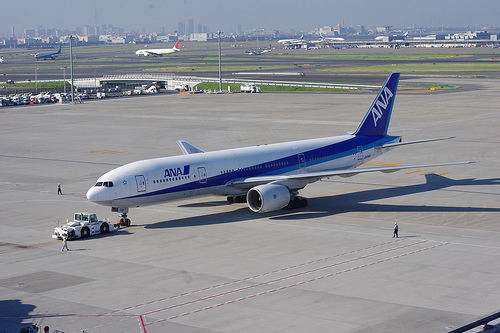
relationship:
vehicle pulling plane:
[53, 209, 116, 241] [69, 65, 477, 217]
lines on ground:
[100, 235, 435, 320] [3, 155, 446, 326]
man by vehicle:
[57, 232, 74, 249] [53, 209, 116, 241]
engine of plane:
[241, 183, 300, 216] [69, 65, 477, 217]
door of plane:
[132, 173, 147, 194] [69, 65, 477, 217]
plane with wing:
[69, 65, 477, 217] [228, 158, 479, 189]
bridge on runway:
[54, 64, 201, 92] [4, 66, 495, 88]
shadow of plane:
[141, 164, 499, 237] [69, 65, 477, 217]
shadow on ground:
[141, 164, 499, 237] [3, 155, 446, 326]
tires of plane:
[114, 213, 133, 227] [69, 65, 477, 217]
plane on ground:
[69, 65, 477, 217] [3, 155, 446, 326]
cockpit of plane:
[92, 180, 118, 191] [69, 65, 477, 217]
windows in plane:
[148, 148, 349, 194] [69, 65, 477, 217]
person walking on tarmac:
[55, 180, 66, 202] [0, 95, 499, 329]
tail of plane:
[352, 68, 456, 150] [69, 65, 477, 217]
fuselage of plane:
[135, 119, 407, 212] [69, 65, 477, 217]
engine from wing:
[241, 183, 300, 216] [228, 158, 479, 189]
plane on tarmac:
[69, 65, 477, 217] [0, 95, 499, 329]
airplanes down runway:
[23, 41, 318, 57] [4, 66, 495, 88]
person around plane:
[55, 182, 63, 196] [69, 65, 477, 217]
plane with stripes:
[69, 65, 477, 217] [259, 141, 329, 173]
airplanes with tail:
[134, 39, 182, 59] [169, 38, 182, 53]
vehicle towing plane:
[53, 209, 116, 241] [69, 65, 477, 217]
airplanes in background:
[23, 41, 318, 57] [9, 47, 488, 50]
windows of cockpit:
[97, 182, 116, 186] [92, 180, 118, 191]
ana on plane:
[160, 167, 185, 178] [69, 65, 477, 217]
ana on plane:
[370, 84, 394, 127] [69, 65, 477, 217]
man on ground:
[57, 232, 74, 249] [3, 155, 446, 326]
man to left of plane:
[57, 232, 74, 249] [69, 65, 477, 217]